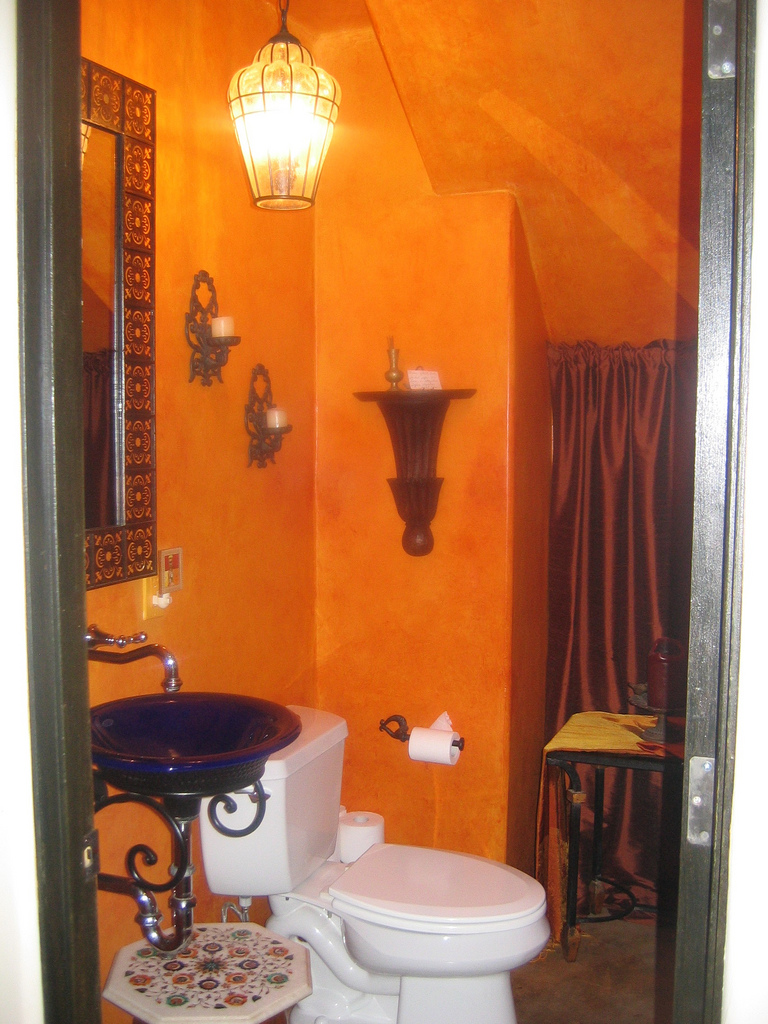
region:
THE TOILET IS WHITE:
[200, 684, 552, 1019]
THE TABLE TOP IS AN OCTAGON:
[99, 911, 337, 1020]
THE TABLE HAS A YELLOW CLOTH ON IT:
[526, 692, 691, 898]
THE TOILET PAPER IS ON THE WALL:
[374, 696, 492, 790]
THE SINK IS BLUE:
[71, 665, 307, 802]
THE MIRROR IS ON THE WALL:
[71, 58, 170, 590]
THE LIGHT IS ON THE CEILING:
[227, 13, 365, 242]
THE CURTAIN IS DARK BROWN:
[533, 315, 693, 920]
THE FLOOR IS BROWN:
[469, 870, 687, 1022]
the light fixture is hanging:
[226, 0, 340, 210]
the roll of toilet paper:
[407, 711, 461, 766]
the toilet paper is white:
[340, 805, 387, 858]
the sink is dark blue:
[89, 686, 299, 771]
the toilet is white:
[200, 703, 549, 1021]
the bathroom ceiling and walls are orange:
[77, 0, 703, 1022]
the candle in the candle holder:
[186, 267, 238, 388]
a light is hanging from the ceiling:
[217, 35, 354, 213]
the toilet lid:
[330, 841, 541, 956]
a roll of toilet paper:
[342, 810, 381, 854]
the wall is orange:
[88, 14, 627, 992]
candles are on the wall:
[182, 263, 304, 497]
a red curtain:
[537, 330, 742, 734]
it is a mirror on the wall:
[49, 86, 174, 572]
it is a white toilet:
[193, 725, 582, 1015]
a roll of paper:
[398, 719, 472, 773]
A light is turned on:
[217, 13, 351, 224]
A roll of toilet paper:
[396, 697, 470, 773]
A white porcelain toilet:
[192, 690, 565, 1016]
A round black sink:
[76, 676, 312, 812]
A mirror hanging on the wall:
[66, 40, 162, 597]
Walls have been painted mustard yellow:
[71, 0, 683, 1018]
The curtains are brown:
[529, 324, 697, 929]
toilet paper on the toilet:
[315, 810, 389, 851]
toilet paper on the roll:
[410, 723, 447, 762]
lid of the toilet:
[380, 872, 465, 910]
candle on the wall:
[242, 386, 292, 460]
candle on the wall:
[390, 361, 456, 392]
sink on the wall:
[85, 633, 188, 693]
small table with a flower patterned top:
[109, 916, 309, 1022]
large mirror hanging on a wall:
[80, 53, 158, 590]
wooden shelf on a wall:
[355, 379, 481, 556]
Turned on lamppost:
[225, 0, 342, 211]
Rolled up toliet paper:
[408, 713, 460, 762]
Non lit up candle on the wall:
[187, 269, 242, 384]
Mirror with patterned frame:
[81, 60, 155, 595]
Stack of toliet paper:
[332, 804, 381, 862]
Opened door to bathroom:
[18, 0, 725, 1022]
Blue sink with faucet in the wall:
[83, 626, 302, 951]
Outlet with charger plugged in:
[142, 547, 183, 616]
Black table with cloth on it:
[532, 714, 692, 960]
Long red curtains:
[548, 347, 696, 943]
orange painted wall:
[93, 11, 687, 1009]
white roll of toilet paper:
[402, 703, 467, 772]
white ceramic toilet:
[185, 672, 561, 1018]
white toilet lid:
[333, 810, 539, 937]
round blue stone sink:
[87, 696, 305, 778]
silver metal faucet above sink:
[87, 624, 189, 702]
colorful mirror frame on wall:
[81, 64, 165, 597]